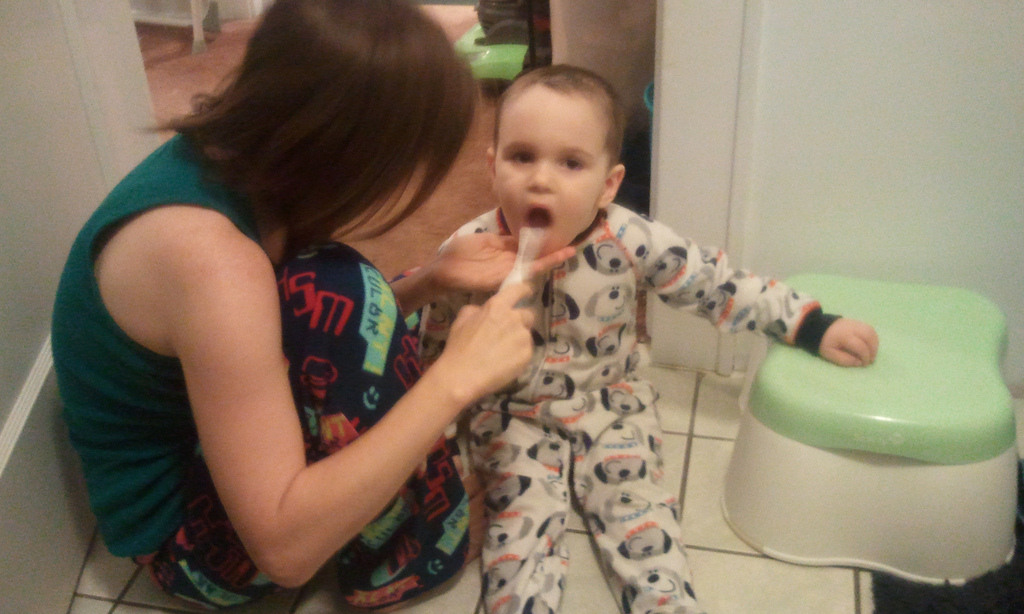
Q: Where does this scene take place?
A: In a bathroom.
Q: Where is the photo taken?
A: In a bathroom.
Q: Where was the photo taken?
A: In a bathroom.